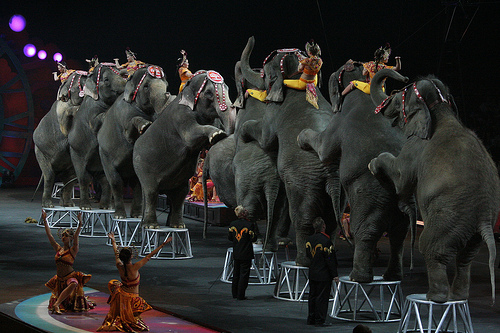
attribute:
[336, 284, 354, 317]
beams — triangular-shaped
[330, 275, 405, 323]
structure — metal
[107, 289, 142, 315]
skirt — orange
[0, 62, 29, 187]
archway — metal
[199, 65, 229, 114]
headdress — red